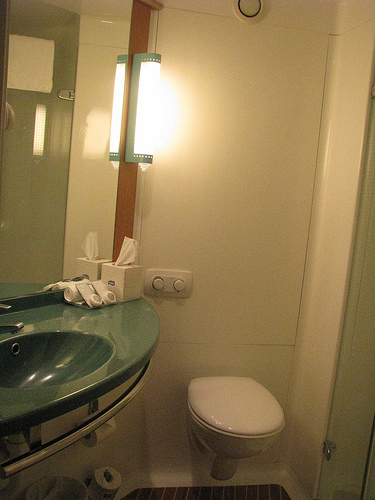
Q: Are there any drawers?
A: No, there are no drawers.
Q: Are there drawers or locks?
A: No, there are no drawers or locks.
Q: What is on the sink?
A: The tissues are on the sink.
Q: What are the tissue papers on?
A: The tissue papers are on the sink.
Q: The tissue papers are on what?
A: The tissue papers are on the sink.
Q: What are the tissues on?
A: The tissue papers are on the sink.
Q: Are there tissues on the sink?
A: Yes, there are tissues on the sink.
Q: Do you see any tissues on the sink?
A: Yes, there are tissues on the sink.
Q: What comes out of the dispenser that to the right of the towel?
A: The tissue papers come out of the dispenser.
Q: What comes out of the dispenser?
A: The tissue papers come out of the dispenser.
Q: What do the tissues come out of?
A: The tissues come out of the dispenser.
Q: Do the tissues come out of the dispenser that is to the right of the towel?
A: Yes, the tissues come out of the dispenser.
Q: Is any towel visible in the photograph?
A: Yes, there is a towel.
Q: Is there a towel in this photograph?
A: Yes, there is a towel.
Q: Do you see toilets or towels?
A: Yes, there is a towel.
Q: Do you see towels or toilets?
A: Yes, there is a towel.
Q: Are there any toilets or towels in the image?
A: Yes, there is a towel.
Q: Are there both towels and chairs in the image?
A: No, there is a towel but no chairs.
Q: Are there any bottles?
A: No, there are no bottles.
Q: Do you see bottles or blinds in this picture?
A: No, there are no bottles or blinds.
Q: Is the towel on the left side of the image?
A: Yes, the towel is on the left of the image.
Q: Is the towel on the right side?
A: No, the towel is on the left of the image.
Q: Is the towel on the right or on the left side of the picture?
A: The towel is on the left of the image.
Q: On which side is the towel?
A: The towel is on the left of the image.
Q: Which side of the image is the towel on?
A: The towel is on the left of the image.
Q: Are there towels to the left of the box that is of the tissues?
A: Yes, there is a towel to the left of the box.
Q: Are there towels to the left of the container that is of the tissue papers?
A: Yes, there is a towel to the left of the box.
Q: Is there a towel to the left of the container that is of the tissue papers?
A: Yes, there is a towel to the left of the box.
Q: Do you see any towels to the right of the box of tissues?
A: No, the towel is to the left of the box.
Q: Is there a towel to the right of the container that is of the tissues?
A: No, the towel is to the left of the box.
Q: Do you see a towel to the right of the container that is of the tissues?
A: No, the towel is to the left of the box.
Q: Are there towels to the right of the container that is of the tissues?
A: No, the towel is to the left of the box.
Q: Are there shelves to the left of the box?
A: No, there is a towel to the left of the box.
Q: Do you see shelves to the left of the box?
A: No, there is a towel to the left of the box.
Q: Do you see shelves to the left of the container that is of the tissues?
A: No, there is a towel to the left of the box.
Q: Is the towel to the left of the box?
A: Yes, the towel is to the left of the box.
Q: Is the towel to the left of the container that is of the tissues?
A: Yes, the towel is to the left of the box.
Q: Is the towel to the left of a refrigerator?
A: No, the towel is to the left of the box.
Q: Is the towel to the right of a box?
A: No, the towel is to the left of a box.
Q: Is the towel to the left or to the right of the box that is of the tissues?
A: The towel is to the left of the box.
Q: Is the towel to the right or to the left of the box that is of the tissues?
A: The towel is to the left of the box.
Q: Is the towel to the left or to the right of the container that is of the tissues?
A: The towel is to the left of the box.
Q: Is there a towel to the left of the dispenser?
A: Yes, there is a towel to the left of the dispenser.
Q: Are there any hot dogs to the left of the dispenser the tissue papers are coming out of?
A: No, there is a towel to the left of the dispenser.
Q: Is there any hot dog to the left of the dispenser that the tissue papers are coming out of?
A: No, there is a towel to the left of the dispenser.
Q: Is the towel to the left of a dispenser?
A: Yes, the towel is to the left of a dispenser.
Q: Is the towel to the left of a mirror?
A: No, the towel is to the left of a dispenser.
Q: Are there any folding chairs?
A: No, there are no folding chairs.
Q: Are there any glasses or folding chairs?
A: No, there are no folding chairs or glasses.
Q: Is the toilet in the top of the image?
A: No, the toilet is in the bottom of the image.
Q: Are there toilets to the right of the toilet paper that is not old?
A: Yes, there is a toilet to the right of the toilet paper.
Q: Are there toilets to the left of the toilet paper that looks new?
A: No, the toilet is to the right of the toilet paper.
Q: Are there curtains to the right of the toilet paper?
A: No, there is a toilet to the right of the toilet paper.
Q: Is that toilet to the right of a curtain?
A: No, the toilet is to the right of a toilet paper.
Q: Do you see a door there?
A: Yes, there is a door.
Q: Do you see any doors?
A: Yes, there is a door.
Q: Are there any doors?
A: Yes, there is a door.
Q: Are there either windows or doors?
A: Yes, there is a door.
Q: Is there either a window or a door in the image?
A: Yes, there is a door.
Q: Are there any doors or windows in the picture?
A: Yes, there is a door.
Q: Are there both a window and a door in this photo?
A: No, there is a door but no windows.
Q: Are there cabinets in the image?
A: No, there are no cabinets.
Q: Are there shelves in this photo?
A: No, there are no shelves.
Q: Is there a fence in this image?
A: No, there are no fences.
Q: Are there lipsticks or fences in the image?
A: No, there are no fences or lipsticks.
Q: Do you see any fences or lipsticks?
A: No, there are no fences or lipsticks.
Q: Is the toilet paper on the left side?
A: Yes, the toilet paper is on the left of the image.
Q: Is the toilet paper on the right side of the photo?
A: No, the toilet paper is on the left of the image.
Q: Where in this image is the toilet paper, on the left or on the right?
A: The toilet paper is on the left of the image.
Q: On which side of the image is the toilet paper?
A: The toilet paper is on the left of the image.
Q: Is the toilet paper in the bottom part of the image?
A: Yes, the toilet paper is in the bottom of the image.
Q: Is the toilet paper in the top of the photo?
A: No, the toilet paper is in the bottom of the image.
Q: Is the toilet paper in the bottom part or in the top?
A: The toilet paper is in the bottom of the image.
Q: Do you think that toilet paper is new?
A: Yes, the toilet paper is new.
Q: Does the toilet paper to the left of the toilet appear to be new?
A: Yes, the toilet paper is new.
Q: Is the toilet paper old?
A: No, the toilet paper is new.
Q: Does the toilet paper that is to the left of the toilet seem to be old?
A: No, the toilet paper is new.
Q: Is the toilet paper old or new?
A: The toilet paper is new.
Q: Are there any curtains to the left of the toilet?
A: No, there is a toilet paper to the left of the toilet.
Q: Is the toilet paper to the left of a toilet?
A: Yes, the toilet paper is to the left of a toilet.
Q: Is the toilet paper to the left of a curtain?
A: No, the toilet paper is to the left of a toilet.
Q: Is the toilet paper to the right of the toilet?
A: No, the toilet paper is to the left of the toilet.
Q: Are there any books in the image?
A: No, there are no books.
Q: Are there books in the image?
A: No, there are no books.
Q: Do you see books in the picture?
A: No, there are no books.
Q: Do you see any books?
A: No, there are no books.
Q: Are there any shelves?
A: No, there are no shelves.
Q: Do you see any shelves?
A: No, there are no shelves.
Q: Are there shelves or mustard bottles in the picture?
A: No, there are no shelves or mustard bottles.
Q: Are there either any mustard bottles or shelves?
A: No, there are no shelves or mustard bottles.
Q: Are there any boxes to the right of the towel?
A: Yes, there is a box to the right of the towel.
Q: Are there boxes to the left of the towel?
A: No, the box is to the right of the towel.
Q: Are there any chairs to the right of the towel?
A: No, there is a box to the right of the towel.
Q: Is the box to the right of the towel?
A: Yes, the box is to the right of the towel.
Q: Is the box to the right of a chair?
A: No, the box is to the right of the towel.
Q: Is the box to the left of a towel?
A: No, the box is to the right of a towel.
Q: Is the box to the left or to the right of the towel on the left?
A: The box is to the right of the towel.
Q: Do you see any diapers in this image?
A: No, there are no diapers.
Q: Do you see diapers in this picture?
A: No, there are no diapers.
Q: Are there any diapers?
A: No, there are no diapers.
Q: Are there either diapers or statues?
A: No, there are no diapers or statues.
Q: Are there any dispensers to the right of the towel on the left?
A: Yes, there is a dispenser to the right of the towel.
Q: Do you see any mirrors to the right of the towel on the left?
A: No, there is a dispenser to the right of the towel.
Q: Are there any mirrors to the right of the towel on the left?
A: No, there is a dispenser to the right of the towel.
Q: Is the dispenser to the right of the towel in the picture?
A: Yes, the dispenser is to the right of the towel.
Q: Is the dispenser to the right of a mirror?
A: No, the dispenser is to the right of the towel.